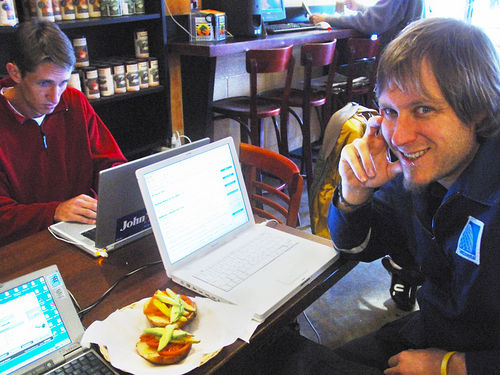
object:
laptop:
[134, 135, 344, 322]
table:
[2, 212, 362, 374]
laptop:
[0, 263, 120, 374]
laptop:
[48, 136, 210, 259]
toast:
[140, 288, 200, 326]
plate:
[97, 295, 228, 375]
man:
[327, 17, 498, 373]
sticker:
[116, 210, 151, 239]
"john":
[120, 214, 148, 234]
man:
[1, 18, 131, 241]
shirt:
[0, 78, 123, 243]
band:
[439, 350, 459, 375]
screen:
[144, 144, 249, 265]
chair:
[237, 141, 305, 230]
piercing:
[410, 159, 415, 167]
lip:
[394, 150, 429, 167]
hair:
[375, 17, 500, 142]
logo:
[454, 216, 484, 266]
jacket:
[329, 137, 500, 374]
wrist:
[433, 350, 465, 375]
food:
[136, 324, 198, 366]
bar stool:
[213, 44, 301, 228]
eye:
[414, 107, 433, 116]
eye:
[382, 107, 398, 116]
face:
[376, 60, 475, 189]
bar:
[169, 23, 380, 157]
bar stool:
[261, 40, 340, 232]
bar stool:
[309, 37, 385, 129]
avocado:
[155, 322, 179, 353]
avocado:
[140, 325, 192, 338]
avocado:
[169, 293, 183, 322]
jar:
[133, 29, 152, 59]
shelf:
[88, 87, 164, 104]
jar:
[74, 35, 92, 67]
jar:
[147, 57, 161, 86]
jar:
[136, 57, 150, 92]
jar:
[96, 65, 117, 97]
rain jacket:
[309, 98, 379, 239]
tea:
[102, 0, 124, 19]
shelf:
[3, 14, 161, 34]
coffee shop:
[0, 1, 499, 374]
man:
[308, 0, 424, 78]